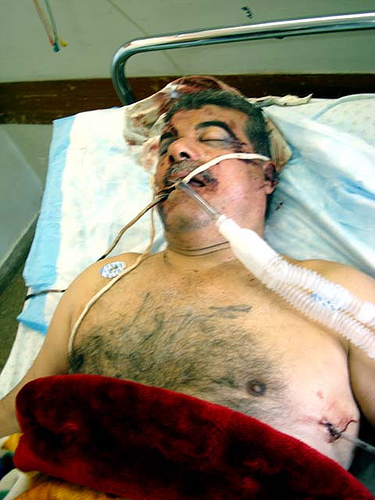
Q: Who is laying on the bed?
A: A sick man.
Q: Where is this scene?
A: A hospital.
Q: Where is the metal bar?
A: Top of bed.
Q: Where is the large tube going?
A: The man's mouth.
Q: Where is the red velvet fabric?
A: On the man's torso.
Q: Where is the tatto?
A: On the man's chest.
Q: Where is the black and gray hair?
A: On the man's head.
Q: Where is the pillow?
A: Under the man's head.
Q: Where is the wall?
A: Above the bed,.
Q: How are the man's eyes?
A: Closed.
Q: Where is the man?
A: Hospital bed.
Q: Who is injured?
A: The man in the bed.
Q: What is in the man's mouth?
A: Tubes.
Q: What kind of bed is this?
A: Hospital bed.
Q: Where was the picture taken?
A: Hospital.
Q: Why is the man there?
A: Treatment.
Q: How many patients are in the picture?
A: One.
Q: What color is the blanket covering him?
A: Red.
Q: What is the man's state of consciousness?
A: Unconscious.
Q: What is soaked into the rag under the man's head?
A: Blood.